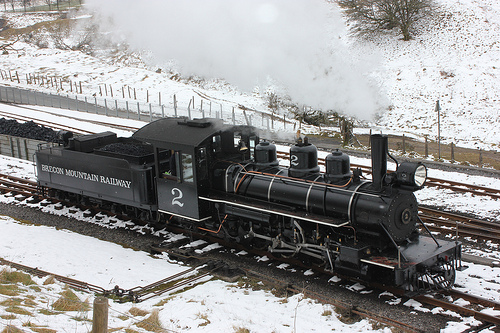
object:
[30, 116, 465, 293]
locomotive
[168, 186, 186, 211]
number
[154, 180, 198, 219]
side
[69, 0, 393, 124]
steam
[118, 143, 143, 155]
coal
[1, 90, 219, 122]
fence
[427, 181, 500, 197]
tracks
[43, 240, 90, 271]
snow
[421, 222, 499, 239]
tracks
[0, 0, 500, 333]
photo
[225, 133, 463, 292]
engine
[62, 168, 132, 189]
mountain railway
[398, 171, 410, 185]
number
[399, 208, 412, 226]
number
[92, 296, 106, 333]
post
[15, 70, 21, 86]
post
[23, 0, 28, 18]
post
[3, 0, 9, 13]
post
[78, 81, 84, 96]
post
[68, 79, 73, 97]
post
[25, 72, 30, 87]
post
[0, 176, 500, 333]
track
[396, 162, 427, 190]
light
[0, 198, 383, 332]
ground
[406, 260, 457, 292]
bumper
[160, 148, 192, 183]
engineer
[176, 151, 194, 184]
window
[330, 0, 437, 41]
tree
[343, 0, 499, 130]
hillside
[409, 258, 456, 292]
cattle guard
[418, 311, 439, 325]
gravel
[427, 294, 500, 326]
tracks